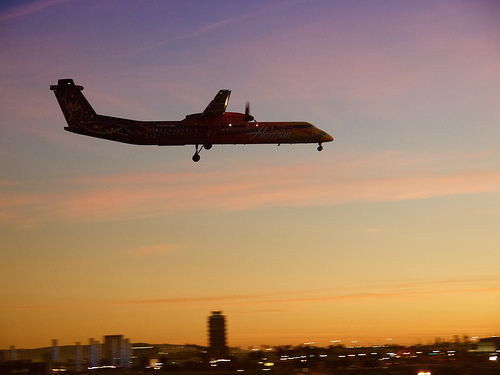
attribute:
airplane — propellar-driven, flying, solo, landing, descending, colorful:
[46, 76, 335, 163]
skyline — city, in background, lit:
[0, 309, 499, 374]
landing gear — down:
[191, 142, 214, 164]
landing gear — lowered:
[316, 142, 326, 152]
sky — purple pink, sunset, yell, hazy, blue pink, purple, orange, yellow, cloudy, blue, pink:
[0, 0, 499, 349]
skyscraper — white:
[117, 336, 136, 372]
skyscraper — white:
[87, 337, 102, 371]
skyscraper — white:
[72, 340, 84, 375]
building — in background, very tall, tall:
[204, 307, 231, 363]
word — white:
[245, 125, 294, 142]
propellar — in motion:
[244, 100, 254, 128]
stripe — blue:
[315, 129, 328, 142]